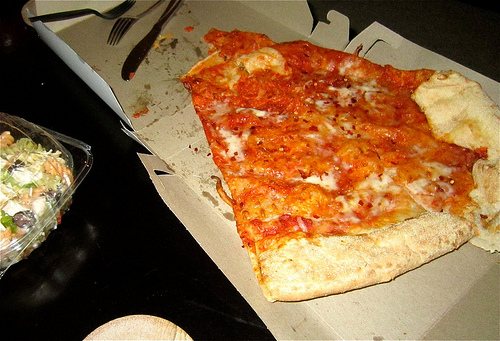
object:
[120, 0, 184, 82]
knife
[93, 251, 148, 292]
wall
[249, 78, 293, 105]
sauce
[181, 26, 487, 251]
cheese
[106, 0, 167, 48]
fork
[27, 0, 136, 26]
utensils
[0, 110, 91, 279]
container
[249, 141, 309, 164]
sauce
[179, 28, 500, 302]
pizza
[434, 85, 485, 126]
crust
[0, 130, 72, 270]
salad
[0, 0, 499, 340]
table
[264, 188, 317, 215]
sauce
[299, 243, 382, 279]
crust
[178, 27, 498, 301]
slice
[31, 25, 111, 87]
trim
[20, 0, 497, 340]
box